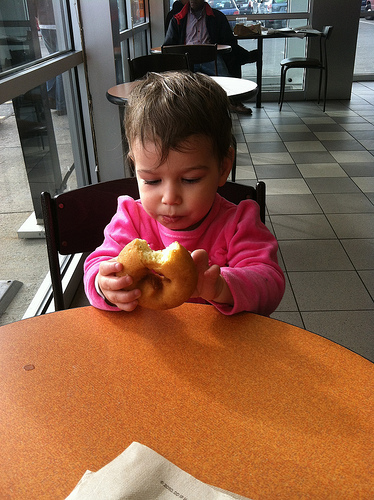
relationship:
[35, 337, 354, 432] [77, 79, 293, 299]
table behind girl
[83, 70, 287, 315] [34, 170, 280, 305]
baby on chair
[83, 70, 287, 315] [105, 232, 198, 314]
baby holds donut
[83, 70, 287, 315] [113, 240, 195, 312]
baby holds donut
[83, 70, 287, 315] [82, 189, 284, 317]
baby wears sweater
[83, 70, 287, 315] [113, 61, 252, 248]
baby has head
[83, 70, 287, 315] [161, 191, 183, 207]
baby has nose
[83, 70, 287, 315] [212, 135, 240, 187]
baby has ear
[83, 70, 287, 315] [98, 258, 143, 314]
baby has hand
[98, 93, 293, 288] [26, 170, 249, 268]
baby sitting in a chair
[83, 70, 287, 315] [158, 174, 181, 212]
baby has nose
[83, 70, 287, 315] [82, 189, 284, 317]
baby wearing sweater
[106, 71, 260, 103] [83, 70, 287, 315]
empty table behind baby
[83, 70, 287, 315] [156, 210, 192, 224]
baby has mouth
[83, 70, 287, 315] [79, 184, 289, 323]
baby wearing shirt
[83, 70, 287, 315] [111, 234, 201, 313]
baby holding donut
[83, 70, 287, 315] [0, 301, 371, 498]
baby sitting at table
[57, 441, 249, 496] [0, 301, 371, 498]
napkin on top of table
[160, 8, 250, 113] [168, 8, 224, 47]
man wearing shirt